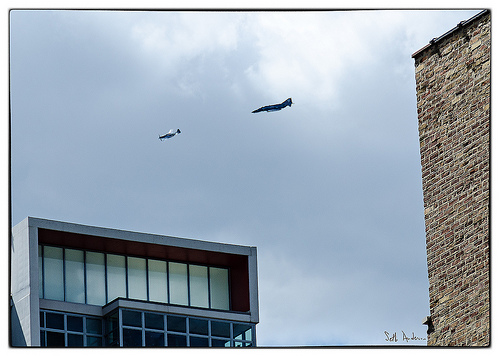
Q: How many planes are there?
A: Two.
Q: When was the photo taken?
A: During the day.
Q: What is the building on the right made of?
A: Brick.